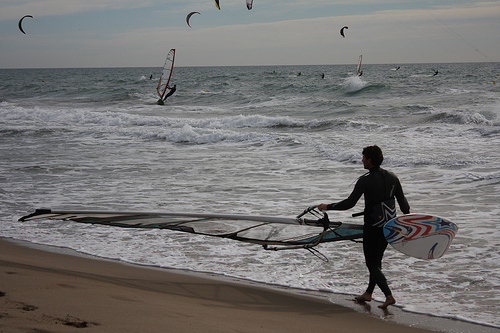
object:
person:
[314, 144, 412, 309]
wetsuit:
[328, 169, 414, 296]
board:
[381, 210, 462, 261]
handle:
[299, 198, 330, 226]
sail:
[12, 207, 388, 264]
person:
[159, 84, 177, 104]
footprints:
[58, 281, 87, 295]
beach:
[0, 240, 421, 332]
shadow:
[0, 245, 354, 321]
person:
[356, 71, 364, 79]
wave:
[344, 67, 375, 106]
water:
[337, 298, 475, 331]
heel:
[385, 294, 397, 305]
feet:
[354, 296, 375, 304]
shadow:
[356, 301, 388, 318]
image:
[1, 0, 498, 333]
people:
[145, 70, 157, 81]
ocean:
[0, 69, 497, 333]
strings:
[183, 15, 355, 84]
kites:
[16, 15, 45, 35]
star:
[437, 219, 452, 227]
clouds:
[379, 6, 491, 51]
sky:
[14, 3, 218, 39]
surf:
[71, 150, 323, 285]